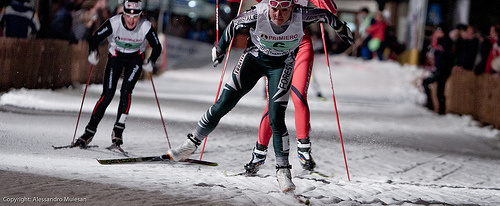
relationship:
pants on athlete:
[184, 52, 295, 168] [51, 2, 177, 156]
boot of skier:
[274, 165, 295, 191] [163, 2, 337, 202]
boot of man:
[296, 142, 316, 169] [244, 0, 338, 174]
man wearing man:
[244, 0, 338, 174] [158, 0, 355, 193]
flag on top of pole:
[310, 0, 337, 19] [316, 20, 352, 181]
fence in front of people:
[388, 37, 472, 84] [348, 0, 480, 78]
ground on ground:
[0, 35, 496, 206] [1, 21, 496, 204]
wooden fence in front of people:
[2, 35, 111, 95] [73, 2, 354, 194]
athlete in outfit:
[51, 2, 177, 156] [71, 16, 170, 146]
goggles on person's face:
[245, 0, 307, 32] [266, 0, 295, 28]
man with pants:
[158, 0, 355, 193] [193, 45, 296, 163]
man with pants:
[244, 0, 338, 174] [249, 36, 310, 157]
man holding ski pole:
[198, 5, 297, 188] [317, 17, 364, 204]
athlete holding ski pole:
[51, 2, 177, 156] [141, 68, 172, 151]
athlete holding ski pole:
[51, 2, 177, 156] [68, 55, 98, 142]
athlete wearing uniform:
[51, 2, 177, 156] [88, 11, 161, 136]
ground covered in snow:
[1, 21, 496, 204] [2, 31, 499, 203]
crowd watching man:
[340, 5, 498, 116] [158, 0, 355, 193]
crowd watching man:
[340, 5, 498, 116] [244, 0, 338, 174]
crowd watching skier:
[340, 5, 498, 116] [77, 1, 162, 145]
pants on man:
[191, 52, 306, 157] [158, 0, 355, 193]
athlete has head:
[51, 2, 177, 156] [120, 2, 145, 31]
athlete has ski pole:
[70, 2, 166, 154] [141, 68, 172, 151]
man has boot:
[158, 0, 355, 193] [165, 138, 198, 162]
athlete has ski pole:
[51, 2, 177, 156] [129, 67, 176, 148]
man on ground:
[244, 0, 338, 174] [0, 35, 496, 206]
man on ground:
[158, 0, 355, 193] [0, 35, 496, 206]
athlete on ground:
[51, 2, 177, 156] [0, 35, 496, 206]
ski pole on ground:
[141, 68, 172, 151] [0, 35, 496, 206]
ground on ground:
[0, 35, 496, 206] [335, 112, 407, 199]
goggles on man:
[267, 1, 292, 9] [158, 0, 355, 193]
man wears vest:
[158, 0, 355, 193] [251, 0, 305, 55]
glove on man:
[342, 26, 355, 45] [158, 0, 355, 193]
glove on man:
[212, 44, 224, 64] [158, 0, 355, 193]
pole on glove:
[204, 4, 222, 64] [210, 44, 224, 63]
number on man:
[266, 38, 288, 56] [158, 0, 355, 193]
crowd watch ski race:
[331, 4, 500, 114] [0, 0, 500, 205]